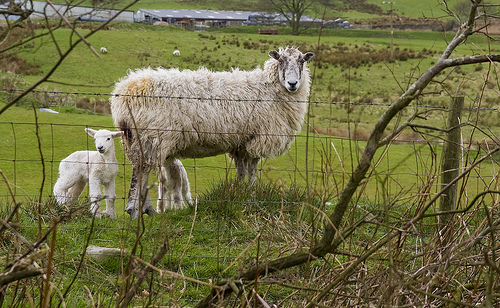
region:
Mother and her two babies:
[54, 33, 359, 225]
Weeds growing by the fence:
[162, 197, 438, 284]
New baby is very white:
[43, 123, 153, 242]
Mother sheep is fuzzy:
[138, 60, 270, 137]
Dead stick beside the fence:
[290, 130, 381, 261]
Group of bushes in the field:
[324, 18, 399, 73]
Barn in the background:
[131, 1, 320, 29]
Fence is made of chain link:
[152, 154, 303, 302]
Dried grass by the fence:
[216, 197, 316, 256]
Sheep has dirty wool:
[115, 67, 150, 98]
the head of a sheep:
[241, 28, 373, 117]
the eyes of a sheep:
[267, 45, 322, 74]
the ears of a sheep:
[259, 37, 321, 82]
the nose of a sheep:
[269, 60, 330, 99]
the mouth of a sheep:
[267, 73, 322, 105]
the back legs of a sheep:
[108, 109, 202, 221]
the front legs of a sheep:
[222, 134, 287, 239]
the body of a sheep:
[133, 16, 319, 151]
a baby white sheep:
[44, 105, 142, 214]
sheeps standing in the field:
[71, 14, 378, 237]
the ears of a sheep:
[259, 42, 328, 62]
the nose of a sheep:
[273, 69, 310, 96]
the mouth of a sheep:
[282, 68, 316, 113]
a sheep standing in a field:
[91, 26, 383, 241]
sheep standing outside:
[19, 31, 478, 307]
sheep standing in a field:
[27, 20, 416, 279]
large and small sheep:
[57, 59, 285, 277]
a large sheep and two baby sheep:
[48, 27, 351, 277]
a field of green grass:
[7, 21, 430, 303]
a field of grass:
[54, 33, 489, 275]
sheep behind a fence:
[17, 10, 445, 306]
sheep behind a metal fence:
[53, 33, 425, 305]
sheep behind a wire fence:
[32, 46, 394, 293]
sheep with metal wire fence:
[72, 49, 404, 307]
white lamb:
[43, 123, 118, 213]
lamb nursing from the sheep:
[142, 146, 199, 212]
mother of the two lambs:
[110, 35, 313, 213]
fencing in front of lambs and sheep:
[1, 85, 459, 307]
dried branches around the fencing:
[0, 107, 497, 307]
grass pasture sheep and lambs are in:
[2, 95, 499, 232]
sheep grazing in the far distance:
[84, 29, 209, 66]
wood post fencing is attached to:
[440, 90, 472, 258]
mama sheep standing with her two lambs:
[25, 30, 325, 220]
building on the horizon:
[128, 5, 356, 27]